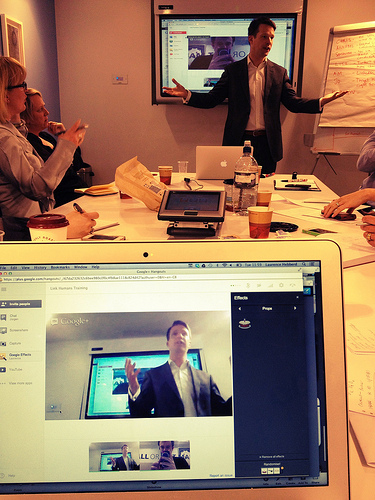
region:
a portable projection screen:
[137, 8, 336, 114]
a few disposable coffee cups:
[242, 174, 282, 246]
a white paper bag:
[113, 145, 171, 217]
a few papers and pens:
[281, 168, 368, 285]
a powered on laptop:
[15, 216, 361, 484]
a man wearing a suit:
[148, 15, 355, 186]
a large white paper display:
[308, 13, 374, 159]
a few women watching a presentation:
[0, 57, 100, 216]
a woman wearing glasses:
[0, 61, 43, 131]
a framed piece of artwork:
[0, 12, 38, 87]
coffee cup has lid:
[22, 203, 88, 247]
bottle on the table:
[236, 145, 271, 217]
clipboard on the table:
[274, 169, 321, 205]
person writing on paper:
[35, 198, 120, 251]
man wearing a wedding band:
[353, 219, 373, 247]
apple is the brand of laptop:
[189, 132, 267, 193]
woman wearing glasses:
[2, 62, 43, 101]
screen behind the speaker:
[167, 24, 310, 123]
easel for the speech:
[324, 30, 373, 167]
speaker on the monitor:
[84, 314, 302, 416]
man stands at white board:
[215, 22, 289, 190]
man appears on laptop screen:
[46, 301, 241, 435]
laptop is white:
[0, 232, 346, 499]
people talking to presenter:
[9, 60, 97, 208]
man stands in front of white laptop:
[192, 136, 260, 194]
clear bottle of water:
[220, 141, 268, 225]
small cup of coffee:
[238, 182, 276, 245]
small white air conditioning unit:
[104, 65, 143, 95]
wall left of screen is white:
[70, 8, 123, 126]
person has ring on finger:
[323, 187, 355, 220]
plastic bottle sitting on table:
[232, 144, 257, 215]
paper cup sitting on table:
[245, 202, 279, 237]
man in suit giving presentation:
[161, 13, 351, 172]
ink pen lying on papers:
[277, 174, 308, 182]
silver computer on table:
[194, 142, 253, 180]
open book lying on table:
[72, 179, 119, 200]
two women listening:
[0, 54, 97, 211]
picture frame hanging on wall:
[0, 11, 31, 69]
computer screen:
[1, 256, 331, 495]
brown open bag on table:
[112, 154, 163, 211]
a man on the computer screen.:
[15, 240, 360, 488]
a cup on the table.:
[241, 197, 275, 235]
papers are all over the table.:
[278, 190, 370, 476]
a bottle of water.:
[227, 141, 259, 212]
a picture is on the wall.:
[0, 10, 33, 65]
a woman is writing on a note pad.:
[0, 177, 120, 237]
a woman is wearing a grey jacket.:
[0, 120, 90, 204]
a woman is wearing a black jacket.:
[30, 129, 52, 151]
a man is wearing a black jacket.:
[212, 19, 293, 147]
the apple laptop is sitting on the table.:
[183, 140, 243, 181]